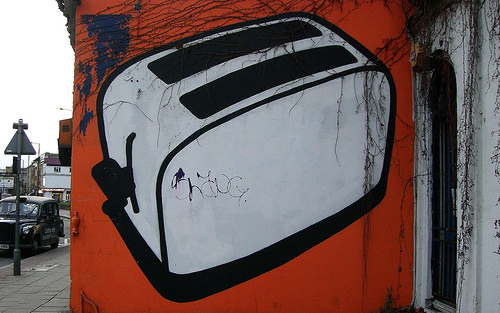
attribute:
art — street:
[109, 36, 343, 283]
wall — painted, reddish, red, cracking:
[103, 10, 482, 282]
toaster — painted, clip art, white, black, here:
[157, 22, 323, 199]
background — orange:
[338, 226, 433, 309]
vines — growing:
[393, 26, 497, 165]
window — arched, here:
[402, 44, 497, 289]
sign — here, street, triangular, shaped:
[11, 119, 46, 166]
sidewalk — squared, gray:
[23, 246, 70, 305]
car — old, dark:
[19, 196, 46, 231]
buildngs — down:
[23, 150, 102, 236]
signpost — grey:
[10, 188, 19, 252]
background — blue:
[88, 19, 123, 56]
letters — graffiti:
[180, 164, 288, 263]